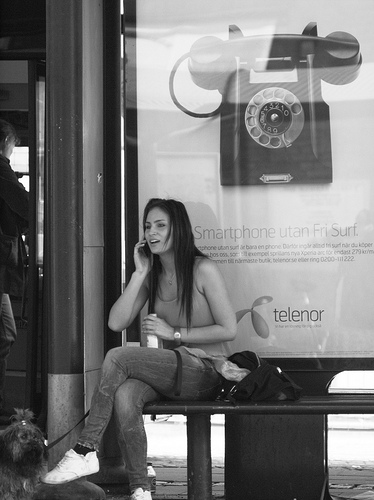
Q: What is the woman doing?
A: Talking on phone.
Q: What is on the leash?
A: Dog.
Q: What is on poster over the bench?
A: Phone.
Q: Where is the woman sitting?
A: Bench.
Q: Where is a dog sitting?
A: On leash by woman's foot.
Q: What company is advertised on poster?
A: Telenor.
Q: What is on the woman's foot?
A: Sneakers.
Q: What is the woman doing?
A: Talking on her phone.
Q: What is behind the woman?
A: A large ad.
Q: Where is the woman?
A: AT bus stop.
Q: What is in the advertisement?
A: An old telephone.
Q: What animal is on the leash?
A: A dog.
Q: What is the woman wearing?
A: A tank top.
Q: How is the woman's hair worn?
A: Down.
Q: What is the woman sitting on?
A: A bench.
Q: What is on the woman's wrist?
A: A watch.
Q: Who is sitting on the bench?
A: The woman.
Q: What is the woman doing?
A: Talking on the phone.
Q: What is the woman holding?
A: A cell phone.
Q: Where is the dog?
A: On the ground.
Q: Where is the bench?
A: Under the woman.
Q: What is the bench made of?
A: Metal.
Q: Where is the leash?
A: On the woman's lap.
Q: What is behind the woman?
A: An advertisement.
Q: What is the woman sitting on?
A: Bench.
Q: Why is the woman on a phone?
A: To talk.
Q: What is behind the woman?
A: Advertisement.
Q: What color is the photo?
A: Black and white.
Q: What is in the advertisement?
A: Phone.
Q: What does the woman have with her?
A: A dog.